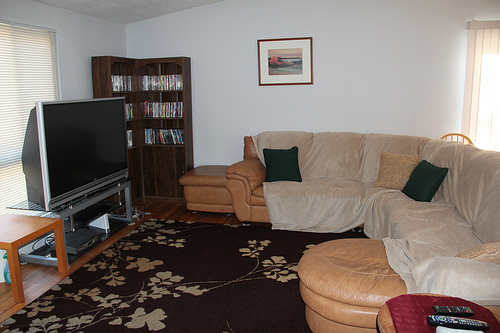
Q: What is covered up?
A: A couch is covered up.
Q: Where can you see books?
A: In the book case by the wwall.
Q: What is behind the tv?
A: White blinds on the window.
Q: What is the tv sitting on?
A: The tv is sitting on a tv stand.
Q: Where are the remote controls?
A: Sitting on the side of the sofa on a table.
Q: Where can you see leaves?
A: They are on the rug on the floor.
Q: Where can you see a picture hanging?
A: Picture is hanging on wall to the right of book case.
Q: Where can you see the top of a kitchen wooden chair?
A: Behind the couch near the window.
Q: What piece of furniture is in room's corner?
A: Bookshelf.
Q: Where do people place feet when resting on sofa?
A: Footrest.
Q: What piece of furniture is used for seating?
A: Couch.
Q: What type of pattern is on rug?
A: Floral.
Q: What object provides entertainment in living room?
A: Television.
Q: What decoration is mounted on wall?
A: Picture.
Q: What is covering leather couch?
A: Sheet.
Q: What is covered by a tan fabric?
A: Couch.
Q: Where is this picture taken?
A: Living room.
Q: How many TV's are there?
A: One.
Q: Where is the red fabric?
A: Under the remotes.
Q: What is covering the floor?
A: Rug.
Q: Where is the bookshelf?
A: In the corner next to the tv.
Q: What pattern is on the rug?
A: Floral.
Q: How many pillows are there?
A: Four.